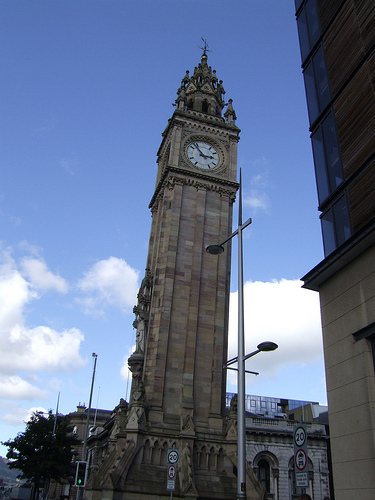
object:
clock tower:
[80, 35, 266, 497]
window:
[253, 449, 279, 498]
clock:
[128, 35, 240, 497]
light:
[206, 242, 224, 253]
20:
[295, 427, 305, 445]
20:
[168, 452, 177, 464]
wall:
[314, 259, 374, 499]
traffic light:
[70, 458, 91, 490]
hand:
[192, 139, 203, 154]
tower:
[121, 35, 238, 410]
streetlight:
[185, 224, 299, 455]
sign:
[292, 423, 307, 488]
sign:
[164, 446, 180, 491]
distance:
[22, 383, 94, 482]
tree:
[6, 406, 92, 498]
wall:
[128, 191, 162, 410]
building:
[43, 36, 375, 498]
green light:
[75, 475, 83, 484]